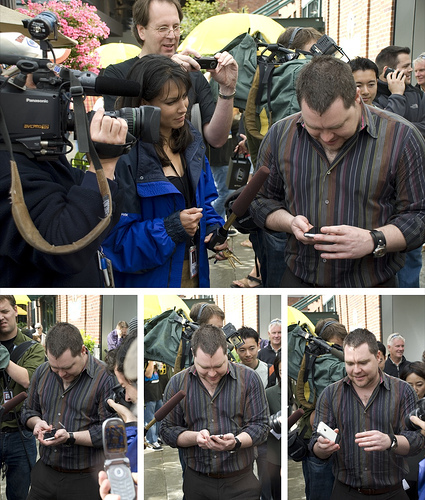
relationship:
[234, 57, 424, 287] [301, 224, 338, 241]
man looking at phone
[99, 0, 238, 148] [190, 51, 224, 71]
man holding camera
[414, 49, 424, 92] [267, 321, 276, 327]
man with hair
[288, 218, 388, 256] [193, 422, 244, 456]
phone in hands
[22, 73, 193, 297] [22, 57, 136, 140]
photographer holding camera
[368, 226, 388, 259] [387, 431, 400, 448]
wrist watch with band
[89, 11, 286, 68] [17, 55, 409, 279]
umbrellas behind gathering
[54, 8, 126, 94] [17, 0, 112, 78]
flowers on a tree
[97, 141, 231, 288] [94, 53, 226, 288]
coat on woman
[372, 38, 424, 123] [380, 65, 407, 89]
man holding cellphone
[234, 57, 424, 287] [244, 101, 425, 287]
man in shirt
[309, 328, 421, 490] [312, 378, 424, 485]
man in striped shirt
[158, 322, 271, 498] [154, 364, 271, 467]
he in striped shirt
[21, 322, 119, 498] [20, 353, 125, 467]
man in striped shirt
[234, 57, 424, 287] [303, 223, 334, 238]
man looking at phone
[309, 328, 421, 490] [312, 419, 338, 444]
man looking at iphone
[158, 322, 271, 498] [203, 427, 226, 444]
he looking at iphone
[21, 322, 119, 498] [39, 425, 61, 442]
man looking at iphone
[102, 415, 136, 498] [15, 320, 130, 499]
cellphone held by man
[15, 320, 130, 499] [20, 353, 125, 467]
man in striped shirt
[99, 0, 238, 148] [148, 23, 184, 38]
man in eyeglasses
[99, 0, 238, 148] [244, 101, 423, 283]
man in shirt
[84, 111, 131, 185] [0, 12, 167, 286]
hand holding camera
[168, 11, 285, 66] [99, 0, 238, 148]
umbrellas to right of man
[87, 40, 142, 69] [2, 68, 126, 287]
yellow umbrella to right of man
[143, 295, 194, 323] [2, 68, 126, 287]
yellow umbrella to right of man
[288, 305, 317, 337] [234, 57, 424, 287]
yellow umbrella to right of man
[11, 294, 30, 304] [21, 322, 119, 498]
yellow umbrella to right of man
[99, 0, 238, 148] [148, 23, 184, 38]
man wearing eyeglasses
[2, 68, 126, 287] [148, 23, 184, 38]
man wearing eyeglasses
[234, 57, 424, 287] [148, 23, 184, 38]
man wearing eyeglasses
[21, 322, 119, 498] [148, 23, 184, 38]
man wearing eyeglasses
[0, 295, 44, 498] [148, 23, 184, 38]
man wearing eyeglasses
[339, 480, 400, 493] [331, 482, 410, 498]
belt with pants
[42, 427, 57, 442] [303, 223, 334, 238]
iphone a phone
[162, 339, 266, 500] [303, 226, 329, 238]
he looking at h phone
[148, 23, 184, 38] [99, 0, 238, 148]
eyeglasses on a man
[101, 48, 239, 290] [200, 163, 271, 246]
woman in a blue jacket holding a microphone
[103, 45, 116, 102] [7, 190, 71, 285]
part of cameraman facing ahead on far left